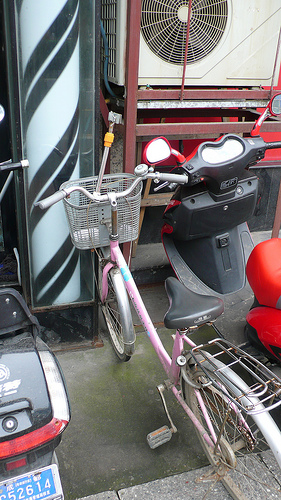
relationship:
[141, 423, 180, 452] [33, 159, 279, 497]
pedal on bicycle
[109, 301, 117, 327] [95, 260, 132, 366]
spokes on wheel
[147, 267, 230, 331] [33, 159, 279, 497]
seat on bicycle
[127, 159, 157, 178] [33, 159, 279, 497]
bell on bicycle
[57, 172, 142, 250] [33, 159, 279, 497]
basket on bicycle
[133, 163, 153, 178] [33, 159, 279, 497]
bell on bicycle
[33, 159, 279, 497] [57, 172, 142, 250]
bicycle with basket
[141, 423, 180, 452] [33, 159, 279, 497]
pedal of bicycle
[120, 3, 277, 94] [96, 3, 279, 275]
air conditioner on stand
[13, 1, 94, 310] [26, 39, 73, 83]
pole with ribbon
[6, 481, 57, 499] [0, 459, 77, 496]
number on plate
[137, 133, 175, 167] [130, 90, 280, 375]
mirror on scooter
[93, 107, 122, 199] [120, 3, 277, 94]
pipe on air conditioner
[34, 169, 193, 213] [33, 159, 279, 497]
handlebars on bicycle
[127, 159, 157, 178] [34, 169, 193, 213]
bell on handlebars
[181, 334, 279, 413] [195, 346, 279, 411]
rack above fender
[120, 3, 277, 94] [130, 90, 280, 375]
air conditioner in front of scooter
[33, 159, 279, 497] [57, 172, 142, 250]
bicycle has basket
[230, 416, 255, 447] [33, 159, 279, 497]
chain on bicycle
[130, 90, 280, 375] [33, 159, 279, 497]
scooter next to bicycle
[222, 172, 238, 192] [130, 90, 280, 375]
logo on scooter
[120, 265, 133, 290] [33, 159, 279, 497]
logo on bicycle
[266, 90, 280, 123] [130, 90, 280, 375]
mirror on scooter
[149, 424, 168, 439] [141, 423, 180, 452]
reflector on pedal